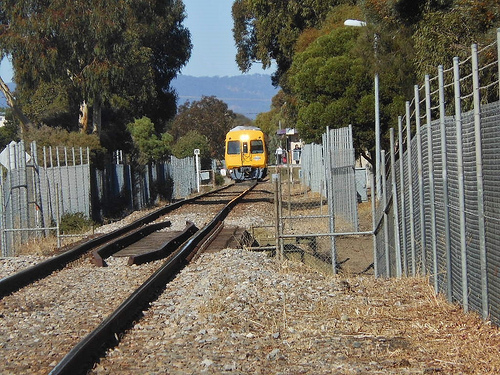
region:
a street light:
[344, 19, 392, 159]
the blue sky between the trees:
[191, 1, 231, 72]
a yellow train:
[223, 130, 264, 176]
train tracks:
[21, 172, 256, 368]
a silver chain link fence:
[283, 182, 369, 267]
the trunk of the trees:
[72, 103, 98, 131]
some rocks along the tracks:
[180, 257, 265, 367]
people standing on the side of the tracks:
[272, 142, 300, 163]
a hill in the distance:
[167, 72, 282, 119]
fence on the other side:
[8, 150, 213, 216]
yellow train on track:
[215, 121, 273, 179]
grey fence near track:
[318, 150, 489, 345]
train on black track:
[0, 151, 247, 343]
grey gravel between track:
[21, 258, 226, 343]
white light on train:
[220, 108, 265, 139]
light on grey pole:
[325, 10, 402, 77]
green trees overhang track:
[228, 4, 498, 142]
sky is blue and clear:
[205, 13, 250, 64]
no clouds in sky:
[188, 14, 236, 69]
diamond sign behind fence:
[0, 147, 47, 184]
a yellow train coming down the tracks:
[222, 122, 267, 180]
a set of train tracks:
[0, 173, 262, 373]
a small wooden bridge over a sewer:
[52, 222, 249, 262]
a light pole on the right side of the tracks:
[339, 15, 395, 272]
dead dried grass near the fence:
[352, 260, 497, 373]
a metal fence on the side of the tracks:
[297, 45, 498, 327]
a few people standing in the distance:
[274, 141, 300, 165]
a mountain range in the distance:
[171, 68, 283, 118]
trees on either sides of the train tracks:
[0, 0, 498, 163]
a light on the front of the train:
[239, 132, 249, 142]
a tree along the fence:
[127, 119, 177, 161]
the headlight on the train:
[237, 133, 247, 138]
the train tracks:
[2, 168, 273, 371]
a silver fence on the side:
[290, 132, 496, 292]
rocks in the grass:
[180, 285, 280, 367]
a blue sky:
[193, 22, 219, 67]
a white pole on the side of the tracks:
[192, 148, 200, 190]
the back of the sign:
[2, 141, 24, 167]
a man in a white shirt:
[275, 147, 283, 165]